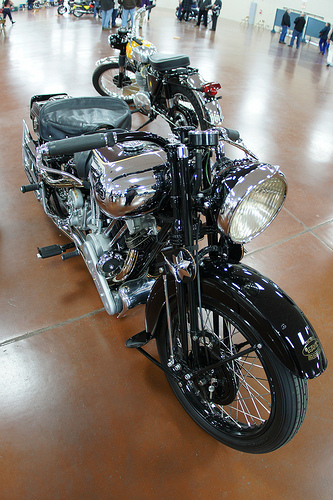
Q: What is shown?
A: A motorcycle.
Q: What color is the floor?
A: Brown.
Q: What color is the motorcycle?
A: Black and silver.